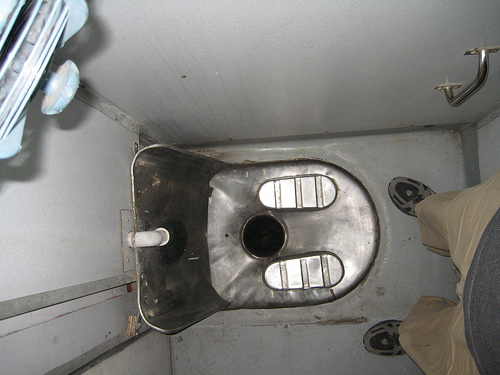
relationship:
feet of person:
[363, 319, 406, 356] [422, 182, 486, 338]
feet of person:
[388, 176, 437, 217] [401, 200, 487, 352]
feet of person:
[358, 324, 397, 352] [430, 182, 490, 342]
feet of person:
[384, 171, 424, 210] [414, 194, 478, 344]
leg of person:
[425, 188, 488, 246] [428, 189, 484, 338]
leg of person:
[395, 299, 453, 375] [430, 182, 490, 342]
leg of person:
[413, 184, 486, 256] [421, 211, 485, 348]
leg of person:
[395, 299, 460, 355] [430, 182, 490, 342]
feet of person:
[363, 319, 406, 356] [422, 190, 488, 310]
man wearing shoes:
[362, 176, 499, 365] [373, 173, 425, 361]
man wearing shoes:
[362, 176, 499, 365] [361, 181, 433, 354]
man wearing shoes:
[362, 176, 499, 365] [364, 179, 432, 363]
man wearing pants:
[362, 176, 499, 365] [399, 190, 483, 367]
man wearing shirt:
[362, 176, 499, 365] [455, 214, 484, 349]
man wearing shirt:
[362, 176, 499, 365] [451, 211, 484, 367]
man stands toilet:
[362, 176, 499, 365] [124, 126, 394, 336]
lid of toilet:
[128, 144, 233, 337] [114, 135, 395, 344]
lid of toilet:
[111, 125, 236, 341] [114, 135, 395, 344]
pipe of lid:
[128, 228, 171, 248] [204, 161, 378, 300]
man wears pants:
[362, 176, 499, 365] [399, 190, 483, 367]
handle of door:
[430, 49, 484, 132] [103, 4, 480, 147]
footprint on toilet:
[257, 174, 338, 212] [124, 126, 394, 336]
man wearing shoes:
[362, 176, 499, 365] [366, 177, 435, 353]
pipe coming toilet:
[128, 210, 170, 250] [125, 110, 394, 343]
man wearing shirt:
[357, 170, 484, 365] [462, 218, 484, 370]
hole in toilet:
[241, 213, 285, 258] [124, 126, 394, 336]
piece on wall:
[111, 307, 145, 343] [1, 73, 172, 370]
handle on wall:
[432, 46, 500, 108] [52, 3, 494, 168]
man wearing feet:
[362, 176, 499, 365] [388, 176, 437, 217]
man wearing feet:
[362, 176, 499, 365] [363, 319, 406, 356]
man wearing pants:
[362, 176, 499, 365] [400, 181, 496, 373]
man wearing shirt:
[362, 176, 499, 365] [458, 202, 496, 372]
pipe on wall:
[128, 228, 171, 248] [1, 73, 172, 370]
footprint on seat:
[262, 251, 349, 290] [200, 156, 375, 306]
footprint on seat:
[259, 166, 338, 218] [200, 156, 375, 306]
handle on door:
[432, 46, 500, 108] [56, 1, 490, 147]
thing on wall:
[3, 0, 99, 157] [0, 44, 163, 373]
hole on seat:
[239, 212, 287, 260] [200, 156, 375, 306]